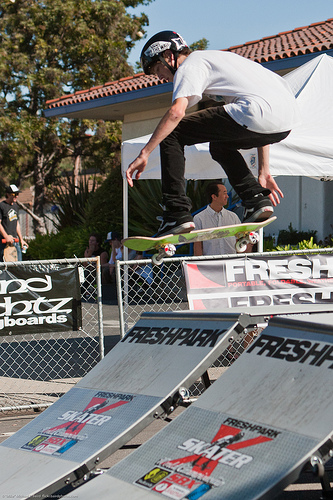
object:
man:
[125, 32, 296, 237]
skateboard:
[119, 215, 278, 264]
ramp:
[3, 311, 245, 499]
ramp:
[55, 311, 332, 499]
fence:
[1, 249, 332, 412]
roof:
[41, 18, 331, 119]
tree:
[0, 0, 147, 242]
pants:
[161, 108, 292, 216]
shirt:
[172, 49, 299, 132]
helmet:
[140, 31, 187, 76]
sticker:
[20, 385, 140, 464]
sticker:
[135, 404, 280, 498]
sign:
[181, 252, 332, 316]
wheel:
[152, 252, 164, 266]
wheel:
[164, 243, 177, 257]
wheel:
[235, 239, 247, 253]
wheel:
[249, 230, 261, 244]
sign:
[0, 262, 84, 339]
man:
[1, 183, 28, 262]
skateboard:
[2, 234, 29, 263]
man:
[192, 182, 246, 257]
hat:
[5, 183, 23, 194]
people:
[76, 231, 109, 301]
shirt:
[0, 200, 20, 240]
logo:
[121, 326, 226, 351]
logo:
[247, 335, 332, 371]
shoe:
[152, 213, 196, 239]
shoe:
[240, 195, 275, 224]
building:
[41, 15, 332, 312]